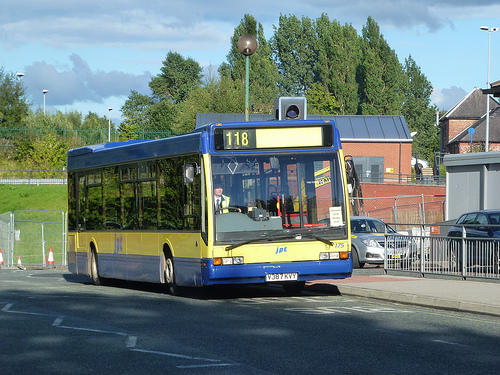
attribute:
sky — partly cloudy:
[1, 0, 498, 134]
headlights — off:
[209, 247, 251, 268]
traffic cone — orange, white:
[42, 246, 57, 266]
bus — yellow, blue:
[64, 117, 354, 294]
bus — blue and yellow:
[39, 107, 364, 307]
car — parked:
[355, 211, 415, 269]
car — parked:
[430, 211, 497, 265]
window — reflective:
[66, 152, 202, 229]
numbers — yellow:
[224, 129, 248, 147]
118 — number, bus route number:
[225, 130, 249, 148]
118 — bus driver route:
[226, 130, 249, 146]